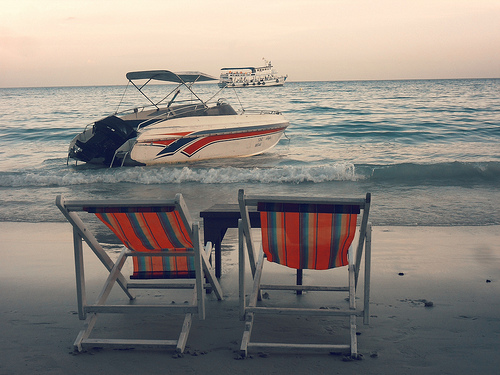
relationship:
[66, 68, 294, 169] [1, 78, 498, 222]
boat in water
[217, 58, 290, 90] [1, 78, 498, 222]
boat in water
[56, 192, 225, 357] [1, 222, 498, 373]
chair on sand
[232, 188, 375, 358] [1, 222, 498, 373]
chair on sand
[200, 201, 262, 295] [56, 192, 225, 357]
table in front of chair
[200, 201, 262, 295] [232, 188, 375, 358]
table in front of chair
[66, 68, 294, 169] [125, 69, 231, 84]
boat has a ca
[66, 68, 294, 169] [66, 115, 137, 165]
boat has a motor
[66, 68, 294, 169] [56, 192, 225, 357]
boat close to chair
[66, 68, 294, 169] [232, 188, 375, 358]
boat close to chair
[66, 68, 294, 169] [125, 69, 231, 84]
boat has a cover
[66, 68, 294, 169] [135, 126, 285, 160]
boat has stripes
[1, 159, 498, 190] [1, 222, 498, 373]
wave coming toward sand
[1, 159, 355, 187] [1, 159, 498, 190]
foam on wave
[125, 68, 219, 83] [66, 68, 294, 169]
canopy on boat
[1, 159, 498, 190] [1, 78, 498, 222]
wave in water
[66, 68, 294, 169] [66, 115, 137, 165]
boat has an motor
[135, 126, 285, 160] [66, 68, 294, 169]
stripes are on boat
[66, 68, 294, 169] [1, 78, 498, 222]
boat on water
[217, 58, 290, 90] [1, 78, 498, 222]
boat on water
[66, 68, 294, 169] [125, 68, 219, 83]
boat has a canopy